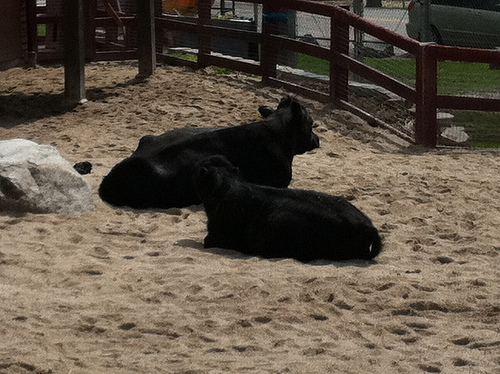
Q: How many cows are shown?
A: Two.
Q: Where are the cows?
A: Pen.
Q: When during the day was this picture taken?
A: Daytime.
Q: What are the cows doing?
A: Lying down.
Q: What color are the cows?
A: Black.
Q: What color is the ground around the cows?
A: Brown.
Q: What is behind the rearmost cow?
A: Rock.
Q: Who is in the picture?
A: No one.